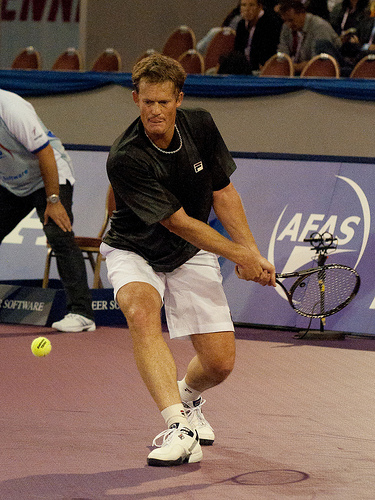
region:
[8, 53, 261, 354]
TWO MEN IN THE PICTURE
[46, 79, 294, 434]
the man is playing baseball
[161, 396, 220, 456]
shoes are white in color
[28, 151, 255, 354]
the man is kicking the ball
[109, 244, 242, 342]
short is white in color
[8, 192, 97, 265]
the pants are black in color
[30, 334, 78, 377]
the ball is yellow green in color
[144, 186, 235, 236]
the t shirt is black in color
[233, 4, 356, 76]
people watching the game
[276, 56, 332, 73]
seats are brown in color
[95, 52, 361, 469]
Person playing tennis at the tennis court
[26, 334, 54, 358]
Tennis ball in mid air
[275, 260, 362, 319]
Tennis racket carried by the person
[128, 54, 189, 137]
Head of the person looking at the tennis ball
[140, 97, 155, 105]
Right eye of the person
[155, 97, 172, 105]
left eye of the person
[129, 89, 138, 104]
Right ear of the person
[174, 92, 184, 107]
left ear of the person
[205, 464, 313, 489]
Shadow of the tennis racket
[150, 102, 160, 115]
Nose of the person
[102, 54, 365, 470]
the man playing tennis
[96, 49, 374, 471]
the man holding the racquet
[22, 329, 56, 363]
the ball in the air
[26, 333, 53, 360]
the ball is lime green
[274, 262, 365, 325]
the racquet is black and gold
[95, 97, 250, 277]
the man wearing the t shirt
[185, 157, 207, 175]
the logo on the shirt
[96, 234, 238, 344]
the man wearing shorts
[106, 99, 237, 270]
the t shirt is black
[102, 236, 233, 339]
the shorts are white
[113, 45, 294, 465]
This is a person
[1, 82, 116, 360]
This is a person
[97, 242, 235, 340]
a pair of white shorts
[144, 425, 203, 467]
a black and white tennis shoe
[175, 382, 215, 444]
a black and white tennis shoe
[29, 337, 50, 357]
a yellow tennis ball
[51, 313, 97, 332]
a black and white tennis shoe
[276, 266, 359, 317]
a black tennis racket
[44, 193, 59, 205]
a silver men's watch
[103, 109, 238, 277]
a man's black shirt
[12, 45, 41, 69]
a padded chair back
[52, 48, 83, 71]
a padded chair back